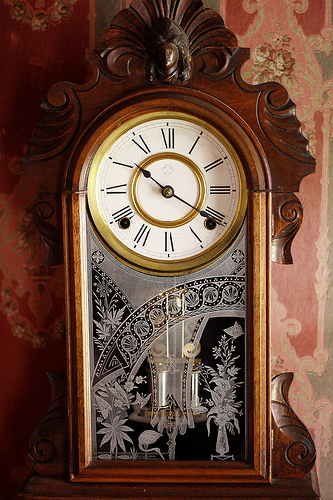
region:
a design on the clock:
[193, 350, 248, 464]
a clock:
[99, 133, 234, 253]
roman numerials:
[188, 138, 236, 210]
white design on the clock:
[125, 303, 163, 338]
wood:
[274, 414, 325, 470]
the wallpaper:
[270, 40, 326, 87]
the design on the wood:
[274, 399, 318, 461]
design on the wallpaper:
[1, 270, 60, 345]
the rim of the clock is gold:
[144, 254, 181, 273]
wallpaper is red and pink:
[263, 9, 315, 31]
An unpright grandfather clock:
[64, 82, 271, 481]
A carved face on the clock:
[157, 41, 177, 69]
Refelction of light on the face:
[164, 45, 174, 64]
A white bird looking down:
[137, 427, 162, 458]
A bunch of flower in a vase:
[211, 362, 237, 424]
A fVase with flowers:
[215, 429, 230, 454]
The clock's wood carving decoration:
[127, 9, 209, 83]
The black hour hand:
[134, 161, 152, 180]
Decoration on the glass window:
[143, 280, 196, 336]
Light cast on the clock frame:
[251, 246, 267, 349]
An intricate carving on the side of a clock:
[266, 370, 318, 480]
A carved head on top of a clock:
[143, 14, 192, 84]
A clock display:
[85, 116, 245, 461]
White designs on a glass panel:
[83, 240, 255, 465]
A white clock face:
[96, 120, 250, 259]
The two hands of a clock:
[132, 165, 224, 231]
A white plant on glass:
[96, 414, 131, 458]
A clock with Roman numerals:
[105, 127, 237, 256]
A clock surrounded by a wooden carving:
[26, 16, 326, 497]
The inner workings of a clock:
[123, 273, 215, 423]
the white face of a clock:
[93, 114, 243, 263]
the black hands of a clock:
[132, 160, 225, 228]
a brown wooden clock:
[12, 0, 326, 499]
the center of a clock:
[158, 182, 177, 200]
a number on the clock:
[157, 123, 178, 152]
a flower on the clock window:
[95, 411, 136, 455]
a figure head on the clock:
[142, 13, 197, 90]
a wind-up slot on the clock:
[116, 214, 134, 231]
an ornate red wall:
[0, 0, 332, 499]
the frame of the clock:
[57, 82, 273, 485]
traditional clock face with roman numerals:
[86, 110, 248, 272]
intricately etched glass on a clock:
[85, 214, 252, 467]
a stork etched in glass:
[138, 428, 167, 459]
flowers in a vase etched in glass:
[194, 322, 244, 459]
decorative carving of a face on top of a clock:
[144, 18, 191, 85]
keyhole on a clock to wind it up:
[119, 216, 131, 229]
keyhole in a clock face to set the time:
[203, 217, 216, 230]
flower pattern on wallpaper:
[251, 34, 294, 81]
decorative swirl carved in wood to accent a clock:
[269, 372, 316, 477]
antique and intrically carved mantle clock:
[22, 0, 315, 484]